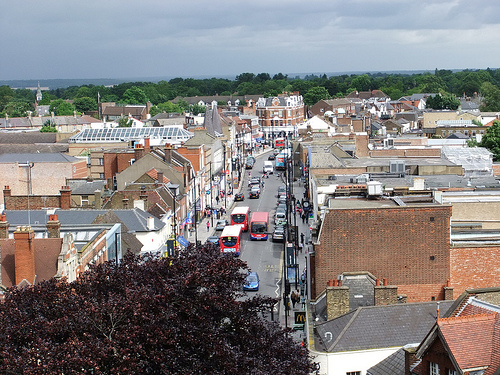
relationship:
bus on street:
[250, 209, 277, 245] [265, 249, 278, 286]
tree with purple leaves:
[68, 287, 219, 363] [25, 290, 93, 371]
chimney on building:
[158, 144, 177, 164] [315, 200, 463, 338]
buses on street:
[218, 205, 272, 263] [265, 249, 278, 286]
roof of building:
[71, 130, 189, 144] [315, 200, 463, 338]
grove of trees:
[278, 80, 468, 91] [134, 79, 272, 95]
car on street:
[238, 264, 269, 295] [265, 249, 278, 286]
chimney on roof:
[158, 144, 177, 164] [71, 130, 189, 144]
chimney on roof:
[13, 227, 39, 275] [71, 130, 189, 144]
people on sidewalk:
[297, 185, 314, 239] [297, 255, 309, 269]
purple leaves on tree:
[25, 290, 93, 371] [68, 287, 219, 363]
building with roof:
[315, 200, 463, 338] [71, 130, 189, 144]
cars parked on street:
[279, 189, 294, 245] [265, 249, 278, 286]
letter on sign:
[171, 236, 195, 265] [290, 308, 310, 337]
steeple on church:
[35, 80, 50, 119] [32, 81, 63, 123]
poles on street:
[283, 173, 308, 330] [265, 249, 278, 286]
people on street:
[297, 185, 314, 239] [265, 249, 278, 286]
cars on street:
[279, 189, 294, 245] [265, 249, 278, 286]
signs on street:
[206, 189, 212, 197] [265, 249, 278, 286]